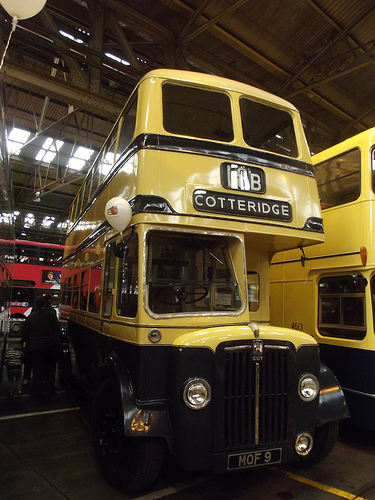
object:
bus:
[54, 68, 347, 493]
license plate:
[226, 446, 285, 473]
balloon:
[104, 195, 131, 232]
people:
[18, 290, 67, 401]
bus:
[2, 235, 106, 341]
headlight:
[296, 370, 321, 403]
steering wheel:
[152, 278, 209, 307]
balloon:
[0, 1, 49, 21]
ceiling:
[2, 1, 375, 156]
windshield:
[141, 228, 248, 318]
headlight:
[183, 376, 212, 411]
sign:
[224, 161, 261, 187]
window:
[160, 79, 238, 144]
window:
[119, 86, 140, 154]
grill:
[217, 343, 294, 450]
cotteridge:
[195, 195, 290, 218]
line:
[274, 465, 366, 499]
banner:
[39, 267, 62, 288]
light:
[293, 432, 314, 453]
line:
[2, 402, 86, 423]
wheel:
[86, 373, 164, 496]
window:
[236, 94, 305, 162]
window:
[114, 231, 137, 323]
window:
[97, 117, 117, 185]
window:
[89, 151, 101, 202]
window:
[82, 170, 94, 215]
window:
[77, 264, 90, 313]